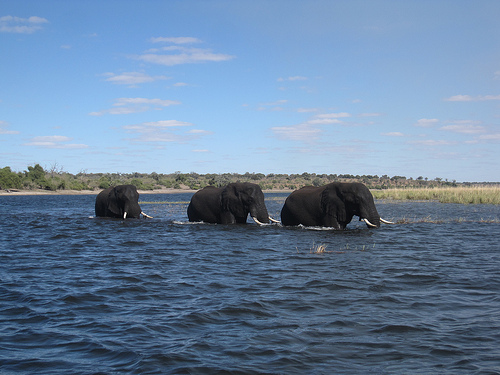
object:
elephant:
[281, 181, 394, 230]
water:
[6, 196, 500, 374]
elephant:
[187, 182, 283, 226]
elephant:
[94, 185, 154, 220]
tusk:
[379, 217, 394, 224]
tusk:
[363, 218, 379, 227]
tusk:
[268, 217, 281, 224]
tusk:
[253, 218, 268, 227]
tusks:
[123, 211, 127, 219]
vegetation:
[2, 163, 499, 201]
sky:
[0, 3, 499, 183]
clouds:
[102, 35, 233, 145]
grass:
[307, 243, 329, 253]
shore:
[16, 185, 499, 200]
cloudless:
[256, 4, 498, 47]